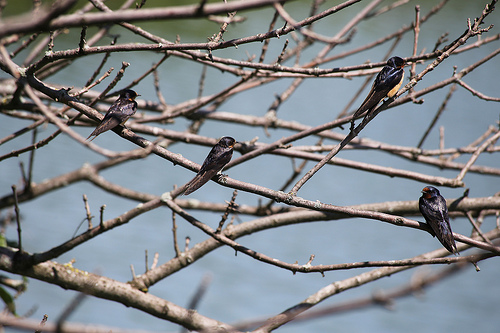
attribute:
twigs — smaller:
[75, 192, 110, 233]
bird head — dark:
[418, 180, 443, 197]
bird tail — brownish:
[183, 166, 220, 198]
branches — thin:
[169, 20, 498, 69]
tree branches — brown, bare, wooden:
[1, 0, 499, 330]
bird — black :
[84, 80, 229, 147]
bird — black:
[176, 131, 238, 202]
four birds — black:
[85, 54, 462, 254]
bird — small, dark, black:
[417, 184, 456, 251]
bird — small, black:
[185, 136, 238, 193]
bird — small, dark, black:
[352, 57, 404, 123]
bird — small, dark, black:
[90, 89, 142, 147]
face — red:
[424, 188, 431, 196]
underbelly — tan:
[389, 70, 404, 98]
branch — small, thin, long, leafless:
[161, 192, 471, 265]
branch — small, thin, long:
[213, 36, 498, 75]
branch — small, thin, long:
[41, 3, 368, 69]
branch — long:
[3, 0, 291, 40]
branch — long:
[6, 94, 461, 189]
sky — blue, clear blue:
[1, 3, 499, 332]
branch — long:
[31, 63, 498, 256]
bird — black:
[352, 56, 411, 122]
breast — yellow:
[388, 75, 402, 96]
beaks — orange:
[424, 187, 430, 197]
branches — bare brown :
[210, 198, 377, 243]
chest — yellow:
[388, 70, 404, 95]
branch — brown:
[284, 110, 354, 144]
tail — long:
[354, 97, 377, 119]